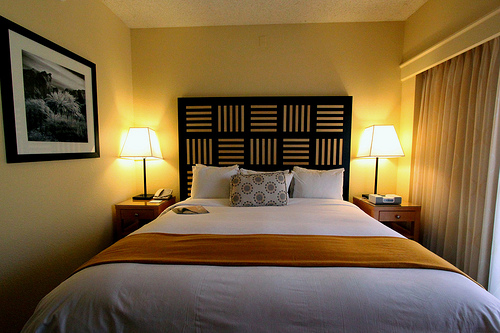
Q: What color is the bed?
A: White.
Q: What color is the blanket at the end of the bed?
A: Brown.